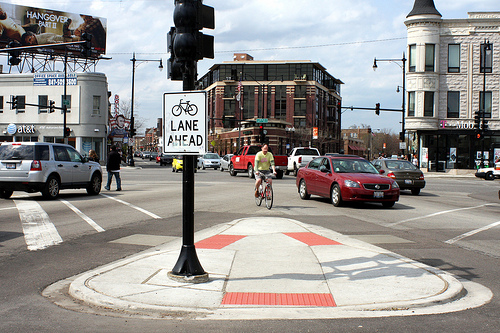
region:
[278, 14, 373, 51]
sky above the land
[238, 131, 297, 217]
person on a bike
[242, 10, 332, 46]
clouds in the sky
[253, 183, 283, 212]
tire on the bike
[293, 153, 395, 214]
red car on the road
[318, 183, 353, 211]
tire of the car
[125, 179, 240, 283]
pole on the ground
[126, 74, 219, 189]
sign on the pole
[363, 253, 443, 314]
shadow on the ground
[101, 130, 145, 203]
person walking across the street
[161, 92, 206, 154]
The writing is in English.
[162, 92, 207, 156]
The writing is in black.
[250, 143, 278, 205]
The man is riding a bike.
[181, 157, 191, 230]
The pole is black.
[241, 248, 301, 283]
The concrete is white.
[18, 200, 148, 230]
The are white lines in the street.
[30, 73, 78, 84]
The poster in the background is blue and white.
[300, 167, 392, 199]
The car in the street is red.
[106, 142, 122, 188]
The man is wearing a black coat.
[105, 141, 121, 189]
The man is wearing blue jeans.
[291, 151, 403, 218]
a red car driving forward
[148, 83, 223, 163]
A black and white sign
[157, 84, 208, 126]
A sign with a bicycle on it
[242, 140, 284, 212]
A man riding a bike in the road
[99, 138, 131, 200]
A man walking in the road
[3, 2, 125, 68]
A large billboard above a building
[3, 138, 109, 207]
A white SUV stopped in traffic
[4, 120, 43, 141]
An AT&T sign on a building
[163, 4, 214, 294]
A stoplight on the concrete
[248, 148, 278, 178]
A man in a yellow shirt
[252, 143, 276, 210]
man riding a bicycle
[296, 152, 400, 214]
a red car driving on a street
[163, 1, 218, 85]
street lights on a black pole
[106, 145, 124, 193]
a pedestrian crossing a street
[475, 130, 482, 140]
a pedestrian orange light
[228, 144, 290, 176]
a red truck driving on the street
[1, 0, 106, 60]
a billboard on top of a building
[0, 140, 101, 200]
a silver car stopped at a light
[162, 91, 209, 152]
a white square panel on a black pole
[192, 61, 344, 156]
a brown building on the corner of a street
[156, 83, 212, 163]
Sign advising of a bike lane.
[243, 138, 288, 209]
Man riding a bicycle.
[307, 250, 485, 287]
Shadows from the sun.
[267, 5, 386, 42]
Blue sky with puffy white clouds.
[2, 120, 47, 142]
The at&t mobile store.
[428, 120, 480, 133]
The T mobile store.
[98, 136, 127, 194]
Man walking across the street.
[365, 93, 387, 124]
Traffic light in the distance.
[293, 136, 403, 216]
Red car on the road.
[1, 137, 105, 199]
A silver truck on the road.